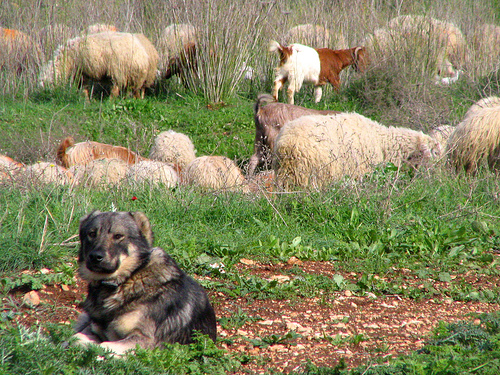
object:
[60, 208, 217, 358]
sheep dog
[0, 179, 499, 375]
grass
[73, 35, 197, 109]
sheep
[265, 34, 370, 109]
goat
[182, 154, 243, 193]
sheep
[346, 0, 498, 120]
daylight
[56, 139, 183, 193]
sheep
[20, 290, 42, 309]
rock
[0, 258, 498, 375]
dirt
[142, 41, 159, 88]
short tail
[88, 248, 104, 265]
black nose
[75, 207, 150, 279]
head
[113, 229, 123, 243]
eye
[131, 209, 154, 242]
ear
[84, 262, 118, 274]
mouth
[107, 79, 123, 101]
leg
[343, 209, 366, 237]
leaf